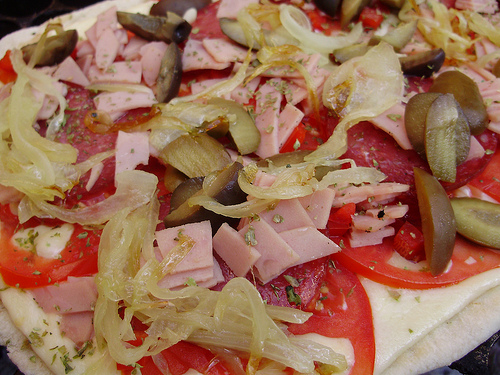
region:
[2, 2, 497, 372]
THERE ARE MANY DIFFERENT KINDS OF FOOD BEING SERVED TOGETHER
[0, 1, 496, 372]
THE PIZZA HAS LOTS OF TOPPINGS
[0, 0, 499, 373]
THIS PANINI LOOKS GOOD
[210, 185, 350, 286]
THIS IS DICED MEAT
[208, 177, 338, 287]
THE MEAT LOOKS LIKE HAM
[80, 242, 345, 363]
THE TOMATOES ARE BRIGHT RED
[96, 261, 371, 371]
THE ONIONS ARE COOKED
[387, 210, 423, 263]
THE RED PEPPERS ARE DICED INTO SMALL PIECES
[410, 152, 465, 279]
THE ARTICHOKES ARE COOKED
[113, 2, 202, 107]
THE OLIVES AND MUSHROOMS ARE DICED UP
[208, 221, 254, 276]
small pink meat piece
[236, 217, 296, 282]
small pink meat piece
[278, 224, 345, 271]
small pink meat piece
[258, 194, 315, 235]
small pink meat piece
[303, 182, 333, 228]
small pink meat piece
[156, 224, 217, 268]
small pink meat piece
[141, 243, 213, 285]
small pink meat piece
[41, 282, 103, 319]
small pink meat piece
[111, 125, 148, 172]
small pink meat piece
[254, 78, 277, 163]
small pink meat piece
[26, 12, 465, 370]
a tray full of food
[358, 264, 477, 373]
the food is on a white surface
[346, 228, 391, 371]
the red part is made of tomatoes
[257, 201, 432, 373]
the red tomatoes gives the food an apetising color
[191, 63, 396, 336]
the food is topped by some green foods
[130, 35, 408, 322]
the green food are the vegetabls t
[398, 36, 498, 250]
the green pepers are cooked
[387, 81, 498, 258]
the green papers are apetissing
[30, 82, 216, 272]
the food is delicious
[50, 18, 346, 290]
pink and chopped meat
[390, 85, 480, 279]
green peppers on plate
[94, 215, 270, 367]
light yellow cooked onions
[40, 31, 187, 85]
dark green olives on plate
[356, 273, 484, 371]
cheese is light yellow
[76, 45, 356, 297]
pink meat is uncooked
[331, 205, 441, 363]
red and soft peppers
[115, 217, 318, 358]
soft and clear onions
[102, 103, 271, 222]
green onions are sliced